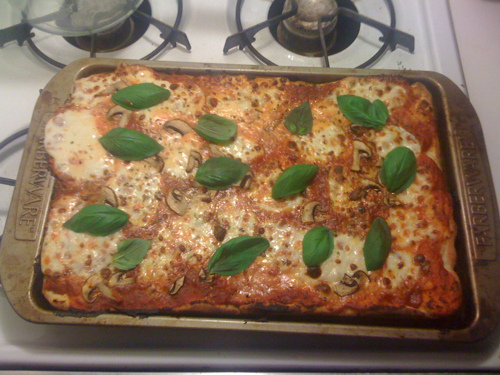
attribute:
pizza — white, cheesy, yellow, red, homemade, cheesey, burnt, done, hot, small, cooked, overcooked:
[70, 72, 444, 321]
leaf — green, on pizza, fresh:
[102, 130, 162, 162]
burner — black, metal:
[237, 3, 397, 62]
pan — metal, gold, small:
[15, 84, 498, 304]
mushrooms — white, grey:
[163, 121, 201, 228]